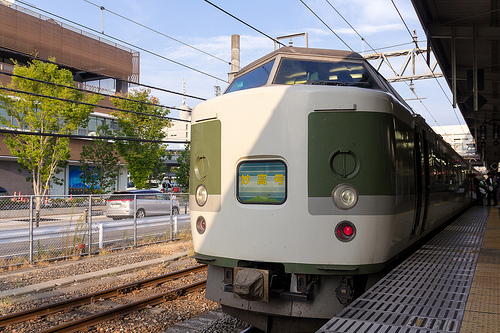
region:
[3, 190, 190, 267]
chain link fence running alongside road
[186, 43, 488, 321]
sleek silver passenger train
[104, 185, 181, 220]
silver minivan parked on the road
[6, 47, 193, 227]
deciduous trees lined up on road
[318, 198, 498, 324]
passenger loading platform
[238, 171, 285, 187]
chinese writing on the front of the train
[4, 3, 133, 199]
large building with parking on top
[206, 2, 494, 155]
electrical wires running above the train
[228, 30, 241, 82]
tall silver rusty smoke stack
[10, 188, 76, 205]
orange cones on the sidewalk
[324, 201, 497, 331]
platform of train station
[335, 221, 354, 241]
round glowing red light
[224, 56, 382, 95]
two windows on train front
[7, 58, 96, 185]
green leaves of tree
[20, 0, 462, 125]
blue sky with clouds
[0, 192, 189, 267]
metal poles on fence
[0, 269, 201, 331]
metal rails of train track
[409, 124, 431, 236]
open doors on train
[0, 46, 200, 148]
four black suspended wires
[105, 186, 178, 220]
side and rear of car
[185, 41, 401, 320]
the front of a train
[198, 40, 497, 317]
a train on the tracks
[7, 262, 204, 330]
a set of tracks next to a train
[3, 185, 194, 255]
a fence next to a train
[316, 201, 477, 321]
a walk way for passengers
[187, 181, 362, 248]
lights on a train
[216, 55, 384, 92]
windows of a train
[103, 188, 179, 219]
a van on a street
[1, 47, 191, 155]
power lines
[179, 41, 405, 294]
the train on the tracks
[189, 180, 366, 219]
the headlights on the train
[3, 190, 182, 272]
the chain link fence beside the tracks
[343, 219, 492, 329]
the platform beside the train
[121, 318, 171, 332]
the gravel on the tracks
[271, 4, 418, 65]
power lines above the train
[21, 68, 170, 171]
trees with green leaves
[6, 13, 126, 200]
the brown building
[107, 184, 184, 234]
the car parked on the street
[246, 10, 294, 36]
the clear blue sky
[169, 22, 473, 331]
Train on the tracks.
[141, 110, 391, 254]
Lights on the train.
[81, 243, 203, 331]
Gravel on the tracks.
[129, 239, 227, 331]
Steel tracks on the road.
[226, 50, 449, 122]
Windows on the train.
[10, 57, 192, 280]
Trees on the road.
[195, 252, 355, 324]
Front of the train.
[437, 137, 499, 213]
People getting on the train.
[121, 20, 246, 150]
Lines over the tracks.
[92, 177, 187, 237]
Car in the background.